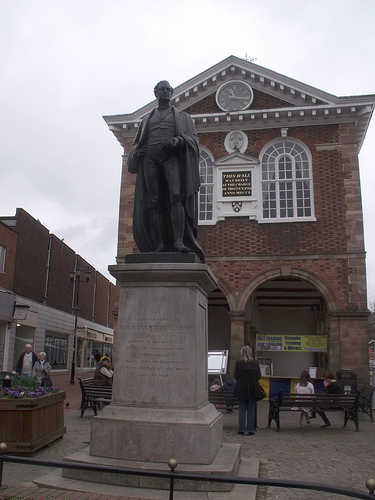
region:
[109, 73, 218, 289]
Statue standing on pedestal.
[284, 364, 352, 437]
Man and woman sitting on bench.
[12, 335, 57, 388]
Man and woman walking down sidewalk.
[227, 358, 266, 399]
Woman dressed in black jacket.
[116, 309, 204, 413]
Engraving on front of concrete pedestal.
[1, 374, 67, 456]
Large square wood container holding flowers.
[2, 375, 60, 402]
Purple flowers growing inside wood container.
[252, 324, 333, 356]
Yellow sign hanging above people.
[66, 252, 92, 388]
Lamp post on sidewalk.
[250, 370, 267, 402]
Woman wearing black purse over shoulder.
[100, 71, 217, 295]
Statue of a prominent historical figure.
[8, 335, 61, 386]
Elderly couple walking towards a flower bed.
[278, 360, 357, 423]
Young couple sitting on a bench.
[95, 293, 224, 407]
Statue base with engraving.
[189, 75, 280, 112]
Clock near the roof of a building.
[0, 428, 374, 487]
Protective fence in front of a statue.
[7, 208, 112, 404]
Arcade next to an historic building.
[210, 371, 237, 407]
Two small children sitting on a bench.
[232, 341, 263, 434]
Woman with a black coat.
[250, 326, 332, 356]
Sign under the alcove of a building.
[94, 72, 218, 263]
Statue in front a building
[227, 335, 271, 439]
Woman is blonde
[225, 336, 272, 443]
Woman has a black jacket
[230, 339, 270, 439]
Woman wears blue jeans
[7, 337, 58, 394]
Old couple walking on street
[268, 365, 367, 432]
couple sitting on a bench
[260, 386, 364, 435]
Bench is brown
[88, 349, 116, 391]
Person sits on a bench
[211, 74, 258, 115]
Clock under roof of building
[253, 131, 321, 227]
Window on right side of building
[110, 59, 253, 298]
a statue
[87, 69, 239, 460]
a statue on a monument of stone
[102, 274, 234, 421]
writing on a stone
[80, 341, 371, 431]
people sit on benches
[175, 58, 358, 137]
a clock on the building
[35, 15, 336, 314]
a cloudy day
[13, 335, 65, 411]
an older couple walk down the street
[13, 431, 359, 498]
a metal railing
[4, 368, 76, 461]
a wooden flower box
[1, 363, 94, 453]
purple flowers in a wooden area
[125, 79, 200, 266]
A statue of a man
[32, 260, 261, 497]
Concrete pedestal supporting a statue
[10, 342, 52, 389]
Old couple walking together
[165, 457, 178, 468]
Gold colored round top of a fence post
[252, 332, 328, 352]
Yellow banner with writing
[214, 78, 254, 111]
Clock on top of a building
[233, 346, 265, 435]
Woman in a black coat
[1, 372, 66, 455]
Planter with purple flowers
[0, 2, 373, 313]
Overcast sky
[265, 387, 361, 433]
Metal and wood bench